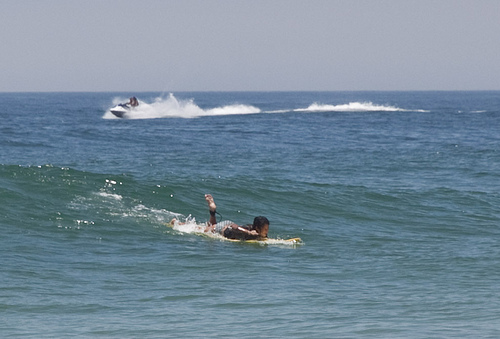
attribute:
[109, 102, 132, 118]
jet ski — white, splashing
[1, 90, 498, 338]
water — blue, splashing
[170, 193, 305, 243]
person — surfing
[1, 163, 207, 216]
wave — rolling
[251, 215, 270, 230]
hair — dark, black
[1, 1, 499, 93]
sky — gray, blue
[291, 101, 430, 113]
wave — white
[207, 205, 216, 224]
leg — up